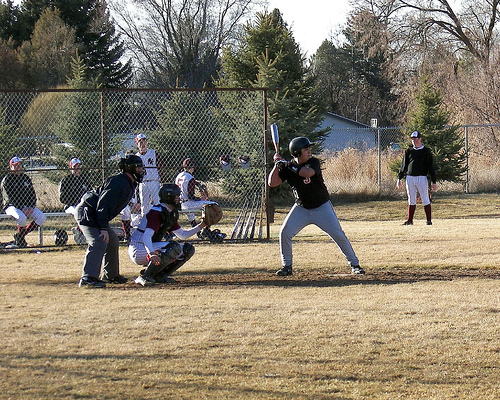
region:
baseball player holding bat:
[254, 118, 387, 291]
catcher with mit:
[126, 179, 245, 296]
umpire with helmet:
[67, 151, 155, 302]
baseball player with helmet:
[257, 119, 374, 286]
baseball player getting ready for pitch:
[258, 120, 371, 287]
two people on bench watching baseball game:
[5, 146, 109, 256]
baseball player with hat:
[127, 131, 182, 243]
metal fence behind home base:
[3, 81, 278, 253]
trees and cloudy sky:
[22, 8, 367, 80]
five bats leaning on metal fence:
[230, 190, 275, 250]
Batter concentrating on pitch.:
[265, 122, 371, 282]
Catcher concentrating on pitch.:
[132, 182, 227, 283]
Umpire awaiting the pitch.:
[65, 144, 143, 305]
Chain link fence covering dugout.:
[1, 89, 272, 241]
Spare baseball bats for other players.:
[228, 188, 269, 245]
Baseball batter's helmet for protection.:
[288, 133, 318, 158]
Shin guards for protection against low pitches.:
[140, 232, 200, 289]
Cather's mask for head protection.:
[155, 182, 189, 212]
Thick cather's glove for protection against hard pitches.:
[201, 199, 226, 229]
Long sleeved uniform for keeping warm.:
[377, 1, 498, 228]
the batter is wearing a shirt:
[273, 153, 337, 214]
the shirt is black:
[276, 152, 333, 212]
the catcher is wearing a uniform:
[122, 202, 208, 279]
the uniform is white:
[128, 201, 200, 274]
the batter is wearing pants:
[275, 192, 362, 270]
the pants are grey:
[273, 193, 368, 280]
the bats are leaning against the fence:
[227, 187, 267, 246]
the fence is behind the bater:
[0, 79, 279, 257]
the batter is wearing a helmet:
[288, 134, 318, 161]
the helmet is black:
[265, 119, 287, 174]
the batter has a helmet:
[283, 127, 326, 164]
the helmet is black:
[285, 132, 321, 162]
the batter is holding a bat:
[263, 115, 284, 188]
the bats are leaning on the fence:
[223, 182, 275, 251]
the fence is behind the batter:
[0, 70, 272, 262]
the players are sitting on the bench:
[0, 201, 217, 261]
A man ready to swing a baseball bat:
[266, 121, 371, 288]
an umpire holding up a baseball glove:
[138, 178, 190, 288]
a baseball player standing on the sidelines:
[392, 128, 439, 227]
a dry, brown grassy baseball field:
[178, 257, 484, 386]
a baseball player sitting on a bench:
[1, 158, 53, 246]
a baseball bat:
[266, 124, 288, 168]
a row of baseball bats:
[228, 194, 266, 241]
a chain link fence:
[8, 124, 268, 237]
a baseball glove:
[200, 199, 230, 231]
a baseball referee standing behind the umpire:
[75, 143, 146, 285]